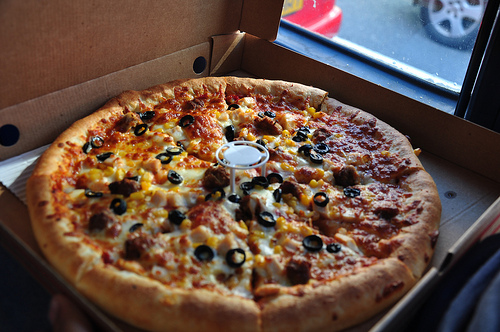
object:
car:
[280, 0, 343, 40]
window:
[275, 2, 484, 97]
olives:
[110, 197, 127, 217]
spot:
[442, 189, 457, 201]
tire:
[419, 0, 484, 48]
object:
[215, 141, 272, 195]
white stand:
[212, 139, 273, 192]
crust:
[205, 76, 402, 147]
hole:
[187, 53, 219, 78]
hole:
[0, 120, 23, 150]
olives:
[164, 167, 182, 183]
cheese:
[152, 119, 337, 257]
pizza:
[23, 75, 444, 330]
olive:
[257, 209, 277, 228]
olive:
[189, 241, 214, 265]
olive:
[297, 142, 322, 164]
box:
[1, 2, 500, 331]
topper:
[215, 139, 268, 190]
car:
[413, 0, 483, 49]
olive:
[240, 182, 254, 191]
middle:
[213, 139, 270, 194]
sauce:
[55, 144, 103, 191]